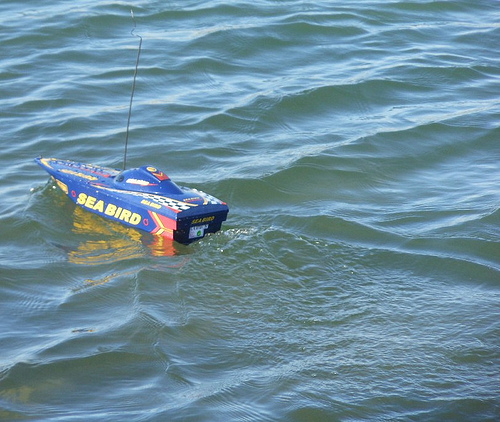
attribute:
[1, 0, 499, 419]
water — wavy, blue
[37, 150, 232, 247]
toy — blue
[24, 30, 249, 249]
boat — toy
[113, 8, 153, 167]
aerial — long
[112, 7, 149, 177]
wire — long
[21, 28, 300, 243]
boat — blue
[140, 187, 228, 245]
designs — colorful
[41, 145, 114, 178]
designs — colorful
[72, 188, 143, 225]
designs — colorful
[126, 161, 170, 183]
designs — colorful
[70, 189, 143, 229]
name — boat, yellow, print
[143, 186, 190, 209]
checkerboard — black, white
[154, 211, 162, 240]
arrow — yellow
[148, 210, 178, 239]
blocks — red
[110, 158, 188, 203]
section — curved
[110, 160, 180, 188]
panel — raised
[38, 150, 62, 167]
curve — yellow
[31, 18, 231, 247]
boat — race, radio controlled, toy, small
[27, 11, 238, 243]
toy — formula one, race boat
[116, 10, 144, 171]
antenna — radio controlled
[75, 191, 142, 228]
name — boat's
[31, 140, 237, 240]
boat — blue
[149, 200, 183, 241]
stripes — red, yellow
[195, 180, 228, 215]
flags — checkered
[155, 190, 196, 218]
flags — checkered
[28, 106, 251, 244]
boat — toy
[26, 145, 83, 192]
head — sharp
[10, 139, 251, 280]
boat — blue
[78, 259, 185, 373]
waves — small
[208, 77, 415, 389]
water — colorless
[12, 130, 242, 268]
boat — plastic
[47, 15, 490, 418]
water — large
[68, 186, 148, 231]
words — yellow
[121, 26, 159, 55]
pole — silver, bent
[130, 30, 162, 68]
tip — pointed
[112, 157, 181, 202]
shape — blue